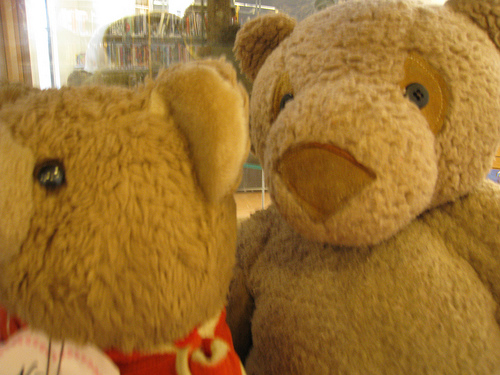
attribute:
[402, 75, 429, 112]
eye — black, button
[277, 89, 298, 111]
eye — black, button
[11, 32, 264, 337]
bear — teddy bear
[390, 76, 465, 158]
eye — black, button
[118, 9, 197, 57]
books — multicolored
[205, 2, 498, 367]
bear — brown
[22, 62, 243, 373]
bear — small, brown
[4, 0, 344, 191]
window — glass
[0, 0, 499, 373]
teddy bears — brown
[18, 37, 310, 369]
bear — brown, dressed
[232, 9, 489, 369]
bear — brown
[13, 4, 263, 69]
background — colorfull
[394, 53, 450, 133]
button — eye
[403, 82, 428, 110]
button eye — blue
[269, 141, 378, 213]
nose — brown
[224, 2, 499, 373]
teddy bear — brown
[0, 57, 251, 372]
teddy bear — teddy bear, red, brown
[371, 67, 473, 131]
eyes — button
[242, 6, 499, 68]
ears — brown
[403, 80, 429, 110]
eye — black, round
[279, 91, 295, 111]
eye — black, round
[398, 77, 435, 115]
eye — button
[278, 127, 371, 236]
nose — long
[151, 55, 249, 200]
ear — large, brown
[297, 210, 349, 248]
mouth — brown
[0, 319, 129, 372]
patch — white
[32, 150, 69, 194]
eye — black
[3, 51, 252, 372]
teddy — brown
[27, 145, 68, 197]
eye — black